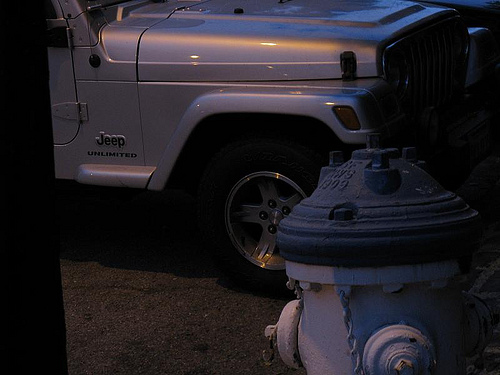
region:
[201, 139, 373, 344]
wheel of the jeep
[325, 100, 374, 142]
red side light indicator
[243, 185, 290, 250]
center part of the wheel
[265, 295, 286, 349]
a nut on the machine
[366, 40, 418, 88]
front light of the jeep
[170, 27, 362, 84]
a light on the jeep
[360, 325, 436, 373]
a big bolt in machine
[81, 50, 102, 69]
a black mark on jeep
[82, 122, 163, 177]
name of the jeep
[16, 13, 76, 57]
a side mirror of the jeep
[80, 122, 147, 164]
THE LOGO SAYS JEEP UNLIMITED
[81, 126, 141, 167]
THE LOGO IS BLACK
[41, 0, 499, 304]
THE JEEP IS GREY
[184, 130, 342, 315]
THE JEEP HAS TIRES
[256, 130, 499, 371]
THE HYDRANT IS NEXT TO THE JEEP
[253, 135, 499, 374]
THE HYDRANT IS GREY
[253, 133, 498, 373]
THE HYDRANT IS CAPPED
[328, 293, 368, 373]
THE HYDRANT HAS A CHAIN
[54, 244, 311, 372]
THE CONCRETE IS DIRTY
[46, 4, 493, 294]
THE JEEP IS PARKED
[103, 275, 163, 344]
this is the ground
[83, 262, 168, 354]
the ground is grey in color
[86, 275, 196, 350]
the ground is clear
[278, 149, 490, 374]
this is a water hose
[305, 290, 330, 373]
the hose is white in color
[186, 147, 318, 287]
this is a wheel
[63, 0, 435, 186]
this is a car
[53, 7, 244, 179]
the car is metallic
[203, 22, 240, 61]
the car is shiny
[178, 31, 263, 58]
the car is white in color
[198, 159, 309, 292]
wheel of the jeep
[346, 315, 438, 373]
nut of the pillar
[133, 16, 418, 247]
a beautiful view of jeep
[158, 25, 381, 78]
light falling on jeep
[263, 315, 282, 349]
a big bolt on pillar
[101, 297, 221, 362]
a small black object in sand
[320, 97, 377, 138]
side indicator of the jeep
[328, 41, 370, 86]
a nut of the jeep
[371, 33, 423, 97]
head light of the jeep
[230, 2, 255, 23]
a small object on the jeep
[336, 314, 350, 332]
the chain is white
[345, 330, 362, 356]
the chain is white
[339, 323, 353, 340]
the chain is white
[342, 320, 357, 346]
the chain is white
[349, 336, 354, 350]
the chain is white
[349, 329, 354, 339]
the chain is white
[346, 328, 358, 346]
the chain is white